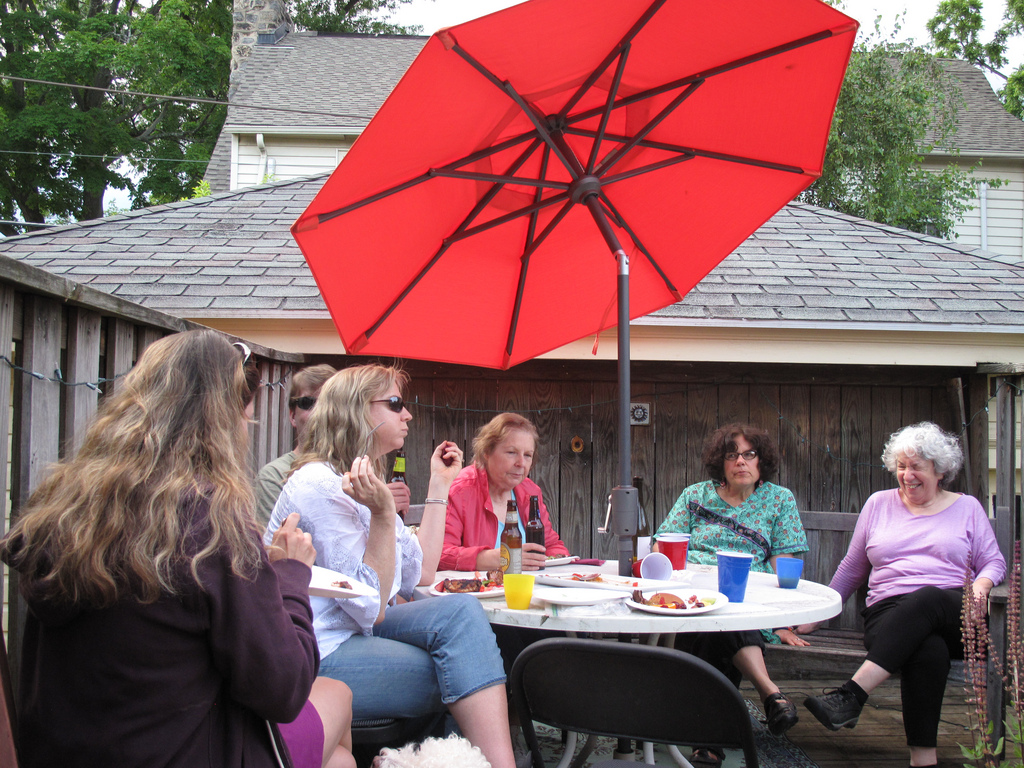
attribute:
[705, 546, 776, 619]
cup — small , blue , disposable 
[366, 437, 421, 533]
bottle — brown , beer 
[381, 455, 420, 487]
label — yellow , small 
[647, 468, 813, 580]
top — green  , floral 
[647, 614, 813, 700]
pants — black 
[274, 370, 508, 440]
sunglasses — black 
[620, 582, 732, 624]
plate — round , white 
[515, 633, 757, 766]
chair — black , metal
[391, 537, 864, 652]
table — white 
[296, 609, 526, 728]
capris — denim 